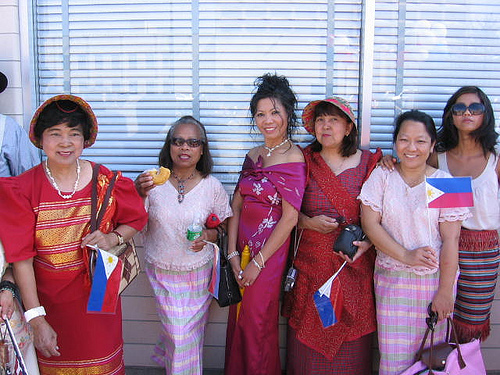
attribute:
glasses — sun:
[449, 101, 484, 118]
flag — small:
[421, 172, 476, 249]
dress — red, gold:
[0, 158, 150, 372]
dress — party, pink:
[220, 154, 308, 372]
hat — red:
[298, 92, 359, 137]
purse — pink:
[396, 312, 484, 372]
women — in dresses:
[2, 70, 481, 370]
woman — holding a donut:
[144, 111, 240, 371]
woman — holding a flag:
[294, 92, 372, 371]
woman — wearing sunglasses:
[446, 98, 485, 118]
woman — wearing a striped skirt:
[431, 83, 484, 336]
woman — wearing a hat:
[297, 92, 378, 368]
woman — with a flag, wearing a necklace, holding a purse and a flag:
[0, 93, 147, 368]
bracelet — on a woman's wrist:
[14, 302, 50, 321]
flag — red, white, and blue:
[425, 172, 475, 212]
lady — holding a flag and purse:
[286, 96, 385, 371]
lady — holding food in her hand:
[128, 116, 231, 371]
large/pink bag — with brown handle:
[396, 314, 484, 372]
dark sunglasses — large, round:
[449, 100, 484, 113]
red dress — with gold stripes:
[0, 160, 152, 373]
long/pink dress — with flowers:
[226, 140, 310, 370]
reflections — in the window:
[35, 0, 252, 94]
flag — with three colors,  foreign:
[422, 173, 477, 213]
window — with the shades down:
[32, 0, 432, 81]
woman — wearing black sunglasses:
[142, 113, 232, 370]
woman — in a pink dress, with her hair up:
[225, 73, 305, 369]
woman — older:
[294, 90, 384, 371]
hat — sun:
[300, 91, 361, 141]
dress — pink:
[228, 141, 305, 371]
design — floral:
[249, 175, 284, 251]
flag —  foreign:
[81, 239, 126, 317]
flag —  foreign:
[313, 274, 351, 324]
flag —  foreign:
[428, 174, 474, 214]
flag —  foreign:
[87, 241, 127, 318]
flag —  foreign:
[426, 172, 474, 218]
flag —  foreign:
[91, 243, 125, 320]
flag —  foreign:
[199, 239, 226, 296]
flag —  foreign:
[308, 269, 349, 329]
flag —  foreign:
[318, 273, 350, 332]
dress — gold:
[39, 210, 96, 356]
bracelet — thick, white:
[22, 307, 47, 322]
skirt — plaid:
[159, 269, 210, 357]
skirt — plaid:
[384, 274, 429, 358]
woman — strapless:
[231, 81, 292, 363]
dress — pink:
[236, 156, 303, 255]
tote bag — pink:
[431, 348, 483, 369]